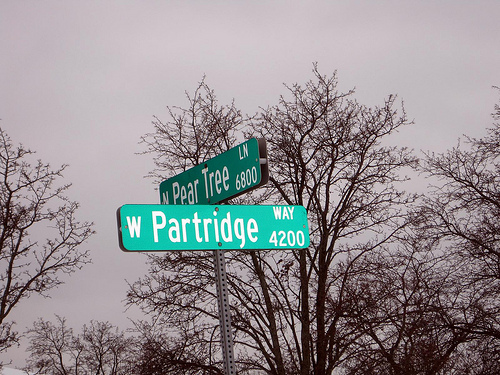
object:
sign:
[149, 137, 269, 205]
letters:
[242, 144, 249, 158]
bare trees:
[228, 62, 433, 375]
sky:
[0, 0, 498, 338]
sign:
[116, 203, 311, 250]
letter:
[151, 211, 167, 242]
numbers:
[268, 230, 306, 247]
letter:
[126, 214, 142, 240]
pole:
[212, 250, 241, 375]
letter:
[219, 210, 236, 242]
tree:
[0, 129, 102, 375]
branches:
[62, 209, 69, 239]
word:
[272, 206, 295, 221]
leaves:
[347, 99, 349, 101]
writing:
[151, 211, 264, 249]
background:
[117, 202, 310, 252]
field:
[0, 0, 500, 375]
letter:
[168, 217, 181, 245]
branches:
[329, 246, 369, 264]